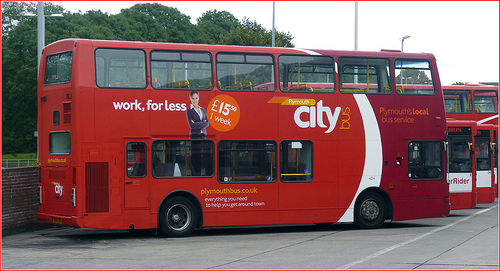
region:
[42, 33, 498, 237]
several red double decker buses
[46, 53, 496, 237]
red buses parked in a parking lot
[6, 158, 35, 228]
red brick wall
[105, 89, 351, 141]
advertisement on double decker bus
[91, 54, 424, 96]
windows on second level of bus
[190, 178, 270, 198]
website of the bus company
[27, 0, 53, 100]
tall silver street light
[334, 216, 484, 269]
white line painted on the street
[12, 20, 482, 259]
photo taken in England of double decker buses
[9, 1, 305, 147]
tall green trees behind buses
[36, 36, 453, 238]
orange, white and red city bus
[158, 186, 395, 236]
small tires on front and back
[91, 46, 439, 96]
six windows on right side top of bus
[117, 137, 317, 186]
four windows on right side bottom of bus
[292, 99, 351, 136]
city bus written on right side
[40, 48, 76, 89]
a rear top glass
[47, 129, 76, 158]
a rear bottom glass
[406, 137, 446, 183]
right side drivers glass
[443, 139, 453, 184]
city bus front windshield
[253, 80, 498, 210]
group of red buses with white Rider labels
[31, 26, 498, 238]
a line of red double decker buses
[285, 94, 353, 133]
a sign that says City bus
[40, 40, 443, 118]
the top level of bus seats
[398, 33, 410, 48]
a street lamp behind the buses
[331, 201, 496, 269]
a white line painted on the road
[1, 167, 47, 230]
a brick wall behind the buses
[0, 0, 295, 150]
a line of trees behind the buses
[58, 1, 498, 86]
cloudy and overcast skies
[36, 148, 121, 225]
the engine cabinet on the back of the bus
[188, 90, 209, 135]
a graphic of a woman on the side of the bus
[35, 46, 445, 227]
bus parked in lot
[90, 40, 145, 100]
window on a bus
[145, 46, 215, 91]
window on a bus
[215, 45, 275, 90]
window on a bus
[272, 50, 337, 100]
window on a bus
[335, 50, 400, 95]
window on a bus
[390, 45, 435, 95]
window on a bus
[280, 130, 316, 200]
window on a bus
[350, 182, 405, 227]
tire on a bus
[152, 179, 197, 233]
tire on a bus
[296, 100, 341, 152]
white letters that spell city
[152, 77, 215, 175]
woman painted on side of bus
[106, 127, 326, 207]
four windows on a bus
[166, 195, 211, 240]
black tire with silver rim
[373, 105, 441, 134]
orange letters on side of bus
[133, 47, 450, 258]
red white andorange bus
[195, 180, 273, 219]
orange and white letters on side of bus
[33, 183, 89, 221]
tail lights on back of bus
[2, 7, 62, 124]
silver pole beside a bus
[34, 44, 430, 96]
top windows of second level of bus